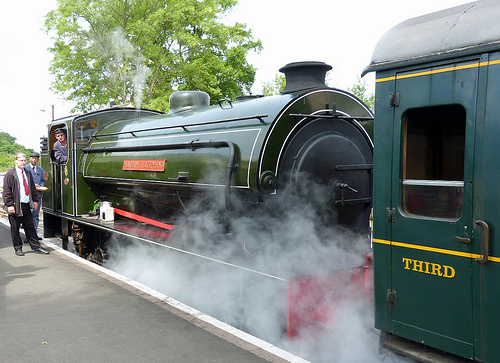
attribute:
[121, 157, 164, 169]
sign — red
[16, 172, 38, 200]
tie — red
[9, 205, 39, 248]
pants — black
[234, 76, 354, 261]
front — black